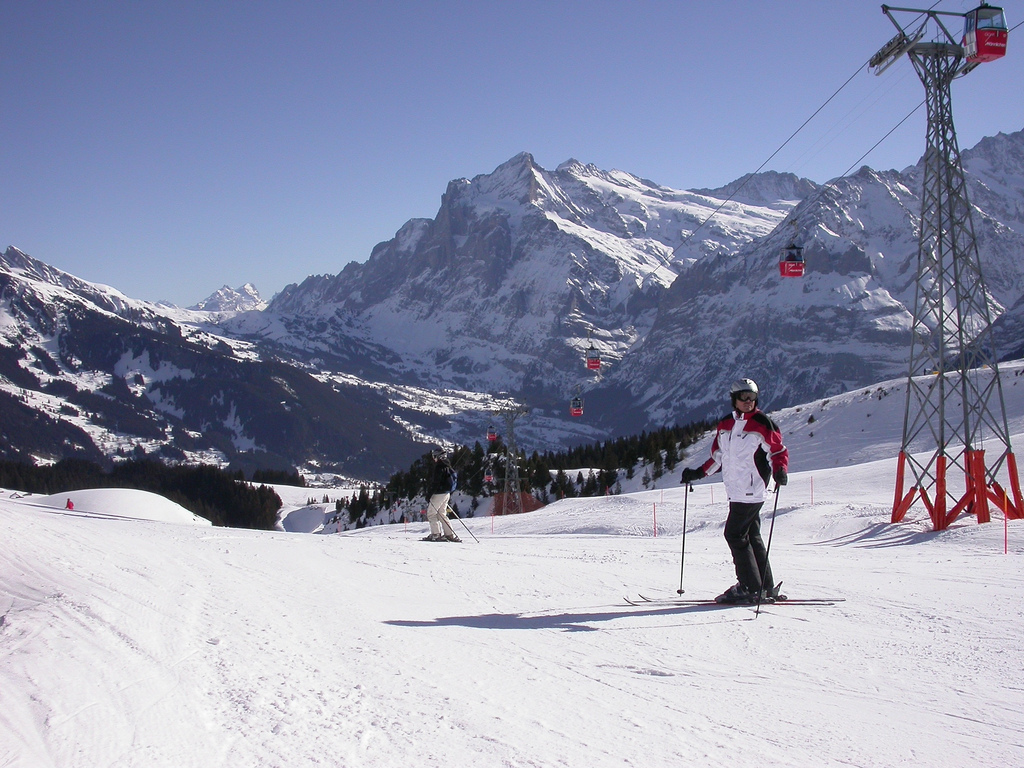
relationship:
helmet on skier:
[725, 378, 760, 402] [680, 374, 791, 588]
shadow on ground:
[385, 601, 772, 630] [732, 690, 769, 719]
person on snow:
[674, 367, 802, 616] [788, 664, 799, 675]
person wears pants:
[674, 367, 802, 616] [720, 500, 781, 587]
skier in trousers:
[406, 440, 461, 542] [423, 491, 452, 531]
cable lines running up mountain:
[475, 7, 1022, 453] [10, 124, 1017, 762]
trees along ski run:
[339, 410, 711, 519] [129, 373, 1024, 717]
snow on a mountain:
[375, 241, 585, 391] [5, 102, 1021, 476]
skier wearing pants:
[406, 440, 461, 542] [422, 493, 464, 535]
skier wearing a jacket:
[406, 440, 461, 542] [422, 452, 461, 496]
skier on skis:
[406, 440, 461, 542] [428, 530, 468, 543]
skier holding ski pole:
[406, 440, 461, 542] [437, 487, 481, 542]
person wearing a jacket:
[675, 372, 803, 617] [696, 414, 794, 510]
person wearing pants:
[674, 367, 802, 616] [725, 502, 767, 609]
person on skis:
[674, 367, 802, 616] [645, 589, 849, 618]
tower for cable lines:
[874, 1, 1019, 529] [477, 7, 1023, 457]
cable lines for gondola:
[477, 7, 1023, 457] [966, 5, 1010, 58]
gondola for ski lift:
[966, 5, 1010, 58] [433, 22, 1017, 530]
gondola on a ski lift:
[952, 5, 1009, 69] [366, 1, 1021, 533]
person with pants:
[674, 367, 802, 616] [720, 502, 779, 598]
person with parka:
[674, 367, 802, 616] [705, 418, 786, 503]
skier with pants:
[407, 439, 462, 541] [426, 494, 459, 534]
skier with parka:
[407, 439, 462, 541] [418, 457, 464, 492]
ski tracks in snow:
[156, 526, 1021, 755] [5, 383, 1019, 762]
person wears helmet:
[674, 367, 802, 616] [728, 363, 776, 405]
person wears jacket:
[675, 372, 803, 617] [672, 404, 815, 508]